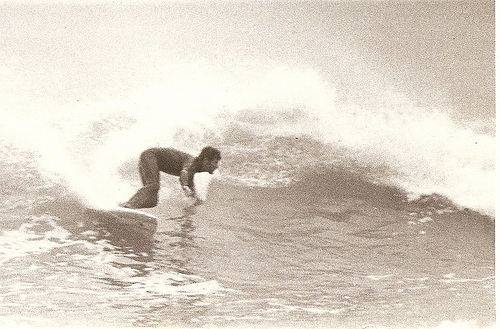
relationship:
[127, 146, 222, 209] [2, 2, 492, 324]
man surfing wave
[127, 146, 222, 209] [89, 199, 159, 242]
man on surfboard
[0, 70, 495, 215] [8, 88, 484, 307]
foam on wave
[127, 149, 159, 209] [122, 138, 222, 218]
legs of surfer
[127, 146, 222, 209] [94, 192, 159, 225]
man on surfboard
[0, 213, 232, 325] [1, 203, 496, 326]
foam on water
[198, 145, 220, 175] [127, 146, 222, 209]
head of man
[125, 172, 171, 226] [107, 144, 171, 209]
legs of surfer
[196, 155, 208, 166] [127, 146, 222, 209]
ear of man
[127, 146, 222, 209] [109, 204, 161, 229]
man leaning on surfboard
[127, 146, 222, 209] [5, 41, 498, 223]
man surfing waves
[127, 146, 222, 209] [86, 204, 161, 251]
man on surfboard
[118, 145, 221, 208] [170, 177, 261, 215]
surfer dragging hand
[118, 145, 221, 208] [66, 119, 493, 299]
surfer in water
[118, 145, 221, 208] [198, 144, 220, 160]
surfer with hair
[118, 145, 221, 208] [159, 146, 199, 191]
surfer with shirt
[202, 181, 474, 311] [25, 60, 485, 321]
calm area in front of wave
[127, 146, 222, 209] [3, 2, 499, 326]
man in water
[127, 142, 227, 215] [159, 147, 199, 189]
man wearing shirt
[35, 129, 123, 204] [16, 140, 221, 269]
water shooting off surfboard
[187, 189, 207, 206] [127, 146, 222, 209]
hand of man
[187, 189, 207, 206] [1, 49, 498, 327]
hand in water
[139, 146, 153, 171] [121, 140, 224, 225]
butt of man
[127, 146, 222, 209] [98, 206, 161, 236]
man on surfboard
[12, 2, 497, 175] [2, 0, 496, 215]
spray from waves